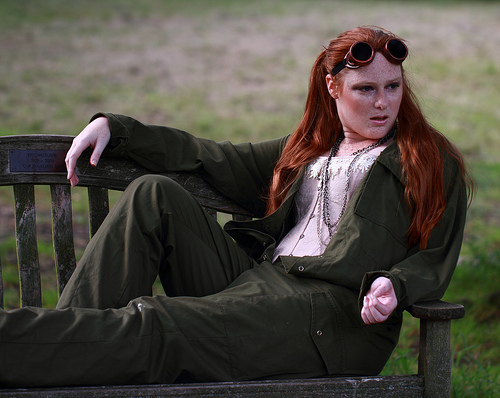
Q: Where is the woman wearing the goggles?
A: On her head.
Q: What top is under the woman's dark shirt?
A: A white tanktop.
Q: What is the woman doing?
A: Posing on a bench.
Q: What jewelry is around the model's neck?
A: Necklaces.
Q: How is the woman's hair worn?
A: Loose.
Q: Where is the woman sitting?
A: On the bench.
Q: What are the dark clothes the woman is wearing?
A: Coveralls.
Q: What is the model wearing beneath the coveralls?
A: A white blouse.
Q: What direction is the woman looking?
A: To the right.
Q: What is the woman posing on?
A: A bench.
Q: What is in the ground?
A: Shadow.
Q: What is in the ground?
A: Grass.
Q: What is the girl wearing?
A: Dress.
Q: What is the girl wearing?
A: Gloves.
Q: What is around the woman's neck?
A: A necklace.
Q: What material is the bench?
A: Wood.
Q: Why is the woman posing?
A: She is a model.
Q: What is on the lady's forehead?
A: Shades.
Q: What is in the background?
A: Grass.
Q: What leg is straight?
A: Left.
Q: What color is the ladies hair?
A: Brunette.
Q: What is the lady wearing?
A: Clothes.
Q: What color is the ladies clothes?
A: Green.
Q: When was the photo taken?
A: Daytime.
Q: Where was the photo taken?
A: On a park bench.